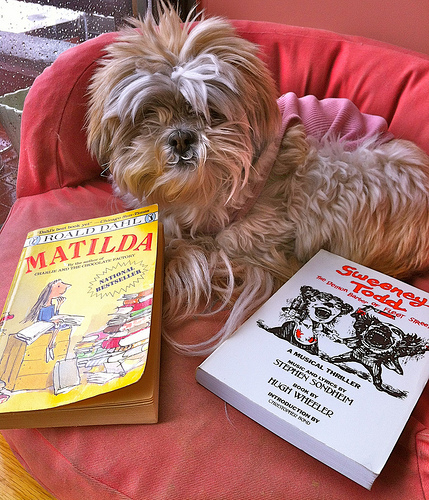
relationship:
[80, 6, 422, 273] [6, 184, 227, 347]
dog on cushion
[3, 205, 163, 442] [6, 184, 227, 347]
book on cushion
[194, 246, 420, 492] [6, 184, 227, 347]
book on cushion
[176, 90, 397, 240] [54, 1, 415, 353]
sweater on dog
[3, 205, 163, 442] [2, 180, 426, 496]
book on cushion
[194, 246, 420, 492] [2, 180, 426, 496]
book on cushion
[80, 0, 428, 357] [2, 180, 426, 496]
dog on cushion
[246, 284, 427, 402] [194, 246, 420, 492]
image on book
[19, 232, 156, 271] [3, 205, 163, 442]
text on book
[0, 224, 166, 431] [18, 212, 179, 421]
pages in book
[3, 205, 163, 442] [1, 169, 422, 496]
book sitting on pillow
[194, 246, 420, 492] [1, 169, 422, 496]
book sitting on pillow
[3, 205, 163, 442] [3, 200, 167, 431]
book with cover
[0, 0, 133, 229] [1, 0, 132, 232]
raindrops clinging on window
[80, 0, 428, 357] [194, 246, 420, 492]
dog sitting next to book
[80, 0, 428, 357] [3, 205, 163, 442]
dog sitting next to book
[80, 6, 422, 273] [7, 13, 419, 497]
dog sitting in chair